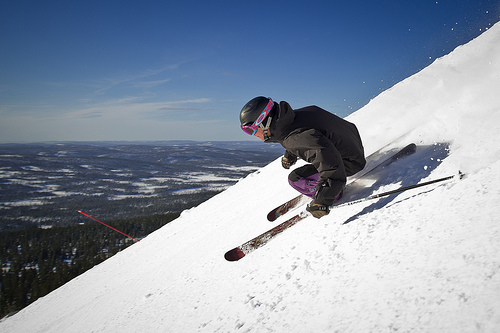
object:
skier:
[237, 89, 365, 218]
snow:
[358, 97, 462, 277]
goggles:
[240, 121, 259, 137]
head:
[236, 94, 283, 142]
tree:
[34, 248, 49, 272]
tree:
[8, 255, 24, 276]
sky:
[3, 5, 401, 72]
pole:
[307, 172, 467, 211]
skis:
[223, 143, 420, 262]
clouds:
[64, 91, 215, 129]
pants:
[287, 166, 347, 204]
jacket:
[268, 99, 366, 207]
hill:
[0, 88, 499, 314]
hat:
[237, 96, 277, 127]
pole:
[73, 208, 142, 243]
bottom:
[3, 282, 28, 297]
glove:
[305, 203, 336, 220]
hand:
[281, 149, 298, 169]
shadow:
[332, 143, 452, 225]